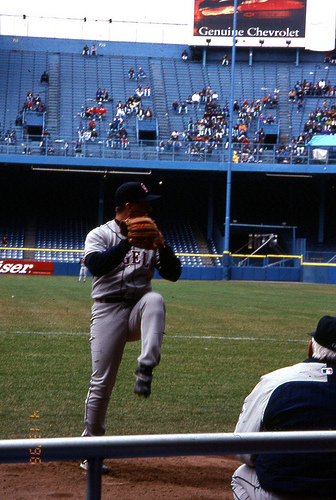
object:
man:
[81, 179, 181, 470]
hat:
[115, 180, 160, 202]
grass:
[197, 342, 222, 372]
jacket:
[235, 359, 336, 491]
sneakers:
[134, 373, 153, 398]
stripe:
[83, 384, 90, 411]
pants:
[80, 298, 163, 443]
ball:
[11, 295, 14, 299]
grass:
[247, 289, 266, 320]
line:
[186, 331, 203, 341]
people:
[173, 92, 211, 134]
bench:
[165, 81, 178, 93]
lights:
[193, 35, 295, 52]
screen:
[191, 0, 305, 34]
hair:
[312, 342, 323, 360]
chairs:
[176, 234, 199, 250]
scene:
[21, 14, 317, 482]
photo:
[14, 71, 316, 446]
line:
[212, 329, 266, 344]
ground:
[37, 377, 198, 429]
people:
[84, 114, 126, 142]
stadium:
[24, 47, 271, 215]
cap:
[308, 316, 334, 348]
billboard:
[202, 34, 230, 36]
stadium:
[0, 212, 66, 306]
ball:
[131, 217, 155, 245]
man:
[230, 312, 336, 500]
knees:
[231, 465, 240, 499]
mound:
[90, 467, 181, 476]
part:
[14, 249, 24, 291]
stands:
[93, 180, 112, 234]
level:
[46, 221, 58, 268]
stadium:
[168, 29, 322, 93]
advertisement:
[194, 29, 304, 38]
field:
[186, 296, 239, 357]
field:
[43, 295, 70, 363]